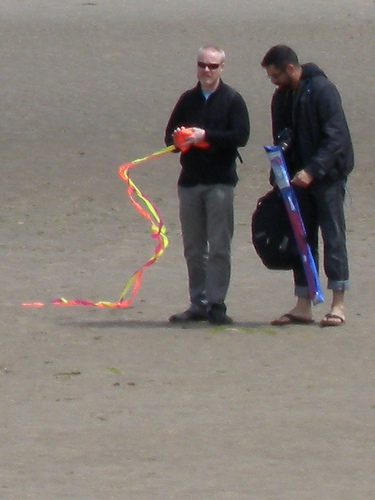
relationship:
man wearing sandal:
[250, 39, 358, 329] [269, 310, 317, 329]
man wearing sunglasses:
[156, 43, 252, 330] [195, 57, 223, 73]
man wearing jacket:
[250, 39, 358, 329] [269, 64, 357, 190]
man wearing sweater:
[156, 43, 252, 330] [160, 75, 250, 190]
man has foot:
[250, 39, 358, 329] [316, 293, 349, 330]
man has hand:
[250, 39, 358, 329] [285, 166, 315, 191]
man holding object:
[250, 39, 358, 329] [257, 141, 329, 306]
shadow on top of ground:
[63, 307, 300, 341] [2, 2, 372, 497]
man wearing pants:
[250, 39, 358, 329] [283, 168, 361, 300]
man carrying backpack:
[250, 39, 358, 329] [248, 179, 323, 272]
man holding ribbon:
[156, 43, 252, 330] [19, 141, 182, 315]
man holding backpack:
[250, 39, 358, 329] [248, 179, 323, 272]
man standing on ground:
[250, 39, 358, 329] [2, 2, 372, 497]